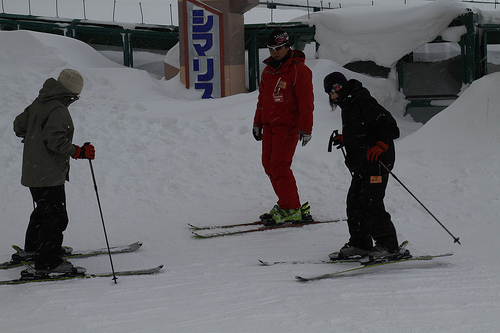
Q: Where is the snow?
A: On the ground.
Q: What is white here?
A: Snow.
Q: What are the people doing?
A: Standing.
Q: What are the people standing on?
A: Skis.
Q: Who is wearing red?
A: A man.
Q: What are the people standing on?
A: SKIS.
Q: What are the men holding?
A: Ski poles.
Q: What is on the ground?
A: Snow.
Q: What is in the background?
A: Sign.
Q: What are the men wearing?
A: Snowsuits.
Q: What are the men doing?
A: Skiing.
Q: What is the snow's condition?
A: Freshly fallen.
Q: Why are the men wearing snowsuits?
A: To keep warm.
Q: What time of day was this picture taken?
A: Dusk.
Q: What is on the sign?
A: Asian characters.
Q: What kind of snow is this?
A: White snow.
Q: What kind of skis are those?
A: Black skis.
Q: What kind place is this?
A: A ski resort.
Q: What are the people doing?
A: Standing.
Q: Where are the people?
A: Ski resort.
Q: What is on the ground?
A: Snow.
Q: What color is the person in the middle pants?
A: Red.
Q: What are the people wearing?
A: Hats.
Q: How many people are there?
A: Three.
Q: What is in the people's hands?
A: Ski sticks.